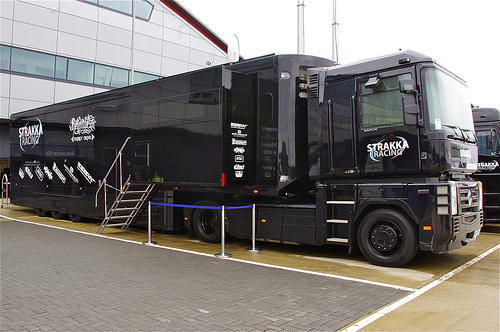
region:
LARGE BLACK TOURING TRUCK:
[7, 37, 498, 263]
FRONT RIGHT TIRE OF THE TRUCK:
[350, 203, 420, 268]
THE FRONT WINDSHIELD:
[417, 62, 475, 147]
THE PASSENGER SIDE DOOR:
[354, 61, 424, 180]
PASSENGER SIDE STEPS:
[320, 179, 357, 257]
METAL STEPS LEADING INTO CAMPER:
[80, 130, 159, 239]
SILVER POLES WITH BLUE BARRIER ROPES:
[137, 192, 267, 267]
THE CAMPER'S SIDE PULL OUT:
[118, 64, 270, 199]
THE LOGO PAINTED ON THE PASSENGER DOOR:
[360, 126, 425, 176]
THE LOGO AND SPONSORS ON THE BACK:
[10, 112, 100, 197]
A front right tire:
[354, 205, 416, 265]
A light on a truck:
[422, 223, 431, 230]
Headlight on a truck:
[449, 183, 458, 214]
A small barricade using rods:
[145, 199, 256, 260]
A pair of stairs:
[92, 135, 154, 237]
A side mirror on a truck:
[399, 90, 421, 127]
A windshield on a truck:
[421, 65, 475, 139]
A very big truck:
[7, 48, 483, 265]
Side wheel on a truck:
[190, 194, 229, 240]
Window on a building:
[10, 46, 55, 79]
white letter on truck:
[363, 138, 375, 153]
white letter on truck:
[371, 143, 379, 150]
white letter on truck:
[376, 140, 383, 150]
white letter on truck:
[382, 140, 389, 150]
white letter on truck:
[387, 140, 396, 150]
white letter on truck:
[401, 135, 408, 152]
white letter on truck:
[376, 148, 384, 155]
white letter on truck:
[396, 146, 405, 155]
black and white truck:
[4, 58, 483, 220]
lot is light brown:
[434, 290, 499, 322]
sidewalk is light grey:
[19, 242, 254, 322]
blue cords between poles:
[146, 189, 247, 216]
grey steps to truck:
[75, 164, 169, 270]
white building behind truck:
[6, 5, 197, 90]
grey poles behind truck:
[276, 5, 332, 57]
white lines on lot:
[326, 238, 483, 330]